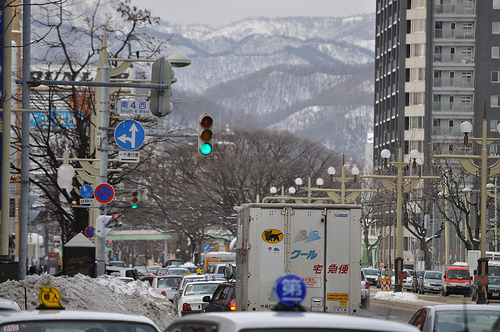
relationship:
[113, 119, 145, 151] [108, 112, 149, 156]
white arrows on blue sign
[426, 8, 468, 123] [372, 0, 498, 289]
windows in building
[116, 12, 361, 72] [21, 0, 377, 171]
snow on mountains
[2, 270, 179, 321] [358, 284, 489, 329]
snow on street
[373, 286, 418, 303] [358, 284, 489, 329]
snow on street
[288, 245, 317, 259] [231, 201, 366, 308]
chinese writing on truck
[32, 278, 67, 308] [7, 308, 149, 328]
sign above car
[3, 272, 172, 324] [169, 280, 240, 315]
snow mound next to car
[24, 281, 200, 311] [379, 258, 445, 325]
dirty snow piled on side roadway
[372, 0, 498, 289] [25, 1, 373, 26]
building stretching into sky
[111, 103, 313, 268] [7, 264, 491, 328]
trees lining middle road way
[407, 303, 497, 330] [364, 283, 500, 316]
car in roadway